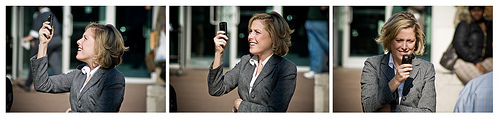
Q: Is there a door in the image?
A: Yes, there is a door.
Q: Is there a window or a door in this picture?
A: Yes, there is a door.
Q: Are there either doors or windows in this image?
A: Yes, there is a door.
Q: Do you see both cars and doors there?
A: No, there is a door but no cars.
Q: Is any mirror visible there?
A: No, there are no mirrors.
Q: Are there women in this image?
A: Yes, there is a woman.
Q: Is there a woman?
A: Yes, there is a woman.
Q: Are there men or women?
A: Yes, there is a woman.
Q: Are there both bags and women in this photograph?
A: Yes, there are both a woman and a bag.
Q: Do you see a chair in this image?
A: No, there are no chairs.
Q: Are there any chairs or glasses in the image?
A: No, there are no chairs or glasses.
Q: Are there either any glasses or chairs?
A: No, there are no chairs or glasses.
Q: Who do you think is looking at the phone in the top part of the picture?
A: The woman is looking at the telephone.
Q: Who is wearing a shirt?
A: The woman is wearing a shirt.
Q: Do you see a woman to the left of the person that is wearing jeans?
A: Yes, there is a woman to the left of the person.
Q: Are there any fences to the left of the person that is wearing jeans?
A: No, there is a woman to the left of the person.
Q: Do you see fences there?
A: No, there are no fences.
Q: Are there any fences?
A: No, there are no fences.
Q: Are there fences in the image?
A: No, there are no fences.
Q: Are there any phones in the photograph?
A: Yes, there is a phone.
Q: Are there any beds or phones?
A: Yes, there is a phone.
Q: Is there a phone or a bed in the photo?
A: Yes, there is a phone.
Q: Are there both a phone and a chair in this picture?
A: No, there is a phone but no chairs.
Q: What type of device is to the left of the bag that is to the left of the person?
A: The device is a phone.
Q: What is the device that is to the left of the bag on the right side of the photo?
A: The device is a phone.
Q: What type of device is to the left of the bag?
A: The device is a phone.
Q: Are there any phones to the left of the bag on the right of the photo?
A: Yes, there is a phone to the left of the bag.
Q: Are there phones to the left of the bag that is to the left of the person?
A: Yes, there is a phone to the left of the bag.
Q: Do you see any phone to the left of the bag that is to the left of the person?
A: Yes, there is a phone to the left of the bag.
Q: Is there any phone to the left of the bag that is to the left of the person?
A: Yes, there is a phone to the left of the bag.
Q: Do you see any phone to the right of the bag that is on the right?
A: No, the phone is to the left of the bag.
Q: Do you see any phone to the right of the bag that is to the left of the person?
A: No, the phone is to the left of the bag.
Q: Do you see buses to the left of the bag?
A: No, there is a phone to the left of the bag.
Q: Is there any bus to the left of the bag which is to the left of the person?
A: No, there is a phone to the left of the bag.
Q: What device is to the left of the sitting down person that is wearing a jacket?
A: The device is a phone.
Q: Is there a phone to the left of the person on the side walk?
A: Yes, there is a phone to the left of the person.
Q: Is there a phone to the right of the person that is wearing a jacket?
A: No, the phone is to the left of the person.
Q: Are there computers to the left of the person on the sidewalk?
A: No, there is a phone to the left of the person.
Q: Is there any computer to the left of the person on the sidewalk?
A: No, there is a phone to the left of the person.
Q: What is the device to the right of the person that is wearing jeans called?
A: The device is a phone.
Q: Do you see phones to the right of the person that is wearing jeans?
A: Yes, there is a phone to the right of the person.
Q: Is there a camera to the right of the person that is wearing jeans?
A: No, there is a phone to the right of the person.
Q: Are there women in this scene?
A: Yes, there is a woman.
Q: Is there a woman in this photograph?
A: Yes, there is a woman.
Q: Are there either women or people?
A: Yes, there is a woman.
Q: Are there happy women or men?
A: Yes, there is a happy woman.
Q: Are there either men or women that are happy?
A: Yes, the woman is happy.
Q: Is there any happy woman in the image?
A: Yes, there is a happy woman.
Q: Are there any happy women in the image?
A: Yes, there is a happy woman.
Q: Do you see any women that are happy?
A: Yes, there is a happy woman.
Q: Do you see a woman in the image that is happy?
A: Yes, there is a woman that is happy.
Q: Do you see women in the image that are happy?
A: Yes, there is a woman that is happy.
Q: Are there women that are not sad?
A: Yes, there is a happy woman.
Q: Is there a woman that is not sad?
A: Yes, there is a happy woman.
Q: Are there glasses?
A: No, there are no glasses.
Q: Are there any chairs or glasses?
A: No, there are no glasses or chairs.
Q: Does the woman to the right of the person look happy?
A: Yes, the woman is happy.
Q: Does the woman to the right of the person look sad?
A: No, the woman is happy.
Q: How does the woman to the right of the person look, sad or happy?
A: The woman is happy.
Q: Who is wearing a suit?
A: The woman is wearing a suit.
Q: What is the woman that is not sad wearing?
A: The woman is wearing a suit.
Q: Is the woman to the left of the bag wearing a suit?
A: Yes, the woman is wearing a suit.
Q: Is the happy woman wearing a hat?
A: No, the woman is wearing a suit.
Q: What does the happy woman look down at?
A: The woman looks down at the telephone.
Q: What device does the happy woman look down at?
A: The woman looks down at the phone.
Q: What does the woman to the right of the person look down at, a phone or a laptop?
A: The woman looks down at a phone.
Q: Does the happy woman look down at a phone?
A: Yes, the woman looks down at a phone.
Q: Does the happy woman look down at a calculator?
A: No, the woman looks down at a phone.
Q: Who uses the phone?
A: The woman uses the phone.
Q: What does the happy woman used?
A: The woman uses a phone.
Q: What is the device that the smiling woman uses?
A: The device is a phone.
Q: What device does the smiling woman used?
A: The woman uses a telephone.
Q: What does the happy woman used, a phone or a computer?
A: The woman uses a phone.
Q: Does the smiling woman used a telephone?
A: Yes, the woman uses a telephone.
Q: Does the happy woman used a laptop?
A: No, the woman uses a telephone.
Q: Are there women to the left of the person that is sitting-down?
A: Yes, there is a woman to the left of the person.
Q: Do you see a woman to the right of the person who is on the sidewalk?
A: No, the woman is to the left of the person.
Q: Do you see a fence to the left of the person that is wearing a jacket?
A: No, there is a woman to the left of the person.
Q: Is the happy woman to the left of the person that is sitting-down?
A: Yes, the woman is to the left of the person.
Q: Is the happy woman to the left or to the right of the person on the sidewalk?
A: The woman is to the left of the person.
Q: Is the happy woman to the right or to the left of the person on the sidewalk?
A: The woman is to the left of the person.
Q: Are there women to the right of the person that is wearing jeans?
A: Yes, there is a woman to the right of the person.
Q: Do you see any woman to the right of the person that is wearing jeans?
A: Yes, there is a woman to the right of the person.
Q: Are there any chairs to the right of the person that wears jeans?
A: No, there is a woman to the right of the person.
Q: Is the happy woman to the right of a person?
A: Yes, the woman is to the right of a person.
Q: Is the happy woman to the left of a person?
A: No, the woman is to the right of a person.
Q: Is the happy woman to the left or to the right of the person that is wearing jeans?
A: The woman is to the right of the person.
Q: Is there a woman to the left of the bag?
A: Yes, there is a woman to the left of the bag.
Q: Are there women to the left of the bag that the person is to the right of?
A: Yes, there is a woman to the left of the bag.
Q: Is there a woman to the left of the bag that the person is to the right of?
A: Yes, there is a woman to the left of the bag.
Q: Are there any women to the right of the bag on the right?
A: No, the woman is to the left of the bag.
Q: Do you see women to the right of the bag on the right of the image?
A: No, the woman is to the left of the bag.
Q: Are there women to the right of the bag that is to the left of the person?
A: No, the woman is to the left of the bag.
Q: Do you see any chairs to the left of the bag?
A: No, there is a woman to the left of the bag.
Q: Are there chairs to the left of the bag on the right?
A: No, there is a woman to the left of the bag.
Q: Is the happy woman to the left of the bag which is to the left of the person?
A: Yes, the woman is to the left of the bag.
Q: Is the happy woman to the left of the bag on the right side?
A: Yes, the woman is to the left of the bag.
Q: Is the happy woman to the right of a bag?
A: No, the woman is to the left of a bag.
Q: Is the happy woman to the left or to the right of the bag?
A: The woman is to the left of the bag.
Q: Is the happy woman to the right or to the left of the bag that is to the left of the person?
A: The woman is to the left of the bag.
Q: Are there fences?
A: No, there are no fences.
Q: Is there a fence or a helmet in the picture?
A: No, there are no fences or helmets.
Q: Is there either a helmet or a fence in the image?
A: No, there are no fences or helmets.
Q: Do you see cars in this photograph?
A: No, there are no cars.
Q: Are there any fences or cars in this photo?
A: No, there are no cars or fences.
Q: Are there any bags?
A: Yes, there is a bag.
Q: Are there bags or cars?
A: Yes, there is a bag.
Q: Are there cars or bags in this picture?
A: Yes, there is a bag.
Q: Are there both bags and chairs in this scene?
A: No, there is a bag but no chairs.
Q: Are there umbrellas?
A: No, there are no umbrellas.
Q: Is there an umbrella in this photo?
A: No, there are no umbrellas.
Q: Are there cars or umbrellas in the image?
A: No, there are no umbrellas or cars.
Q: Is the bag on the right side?
A: Yes, the bag is on the right of the image.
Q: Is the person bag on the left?
A: No, the bag is on the right of the image.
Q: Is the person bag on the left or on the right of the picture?
A: The bag is on the right of the image.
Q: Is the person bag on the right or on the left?
A: The bag is on the right of the image.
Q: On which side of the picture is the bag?
A: The bag is on the right of the image.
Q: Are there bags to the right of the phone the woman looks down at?
A: Yes, there is a bag to the right of the phone.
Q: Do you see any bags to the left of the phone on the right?
A: No, the bag is to the right of the phone.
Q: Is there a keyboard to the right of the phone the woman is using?
A: No, there is a bag to the right of the telephone.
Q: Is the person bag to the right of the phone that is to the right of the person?
A: Yes, the bag is to the right of the phone.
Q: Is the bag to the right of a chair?
A: No, the bag is to the right of the phone.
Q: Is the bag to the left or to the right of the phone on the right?
A: The bag is to the right of the telephone.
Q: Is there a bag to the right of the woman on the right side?
A: Yes, there is a bag to the right of the woman.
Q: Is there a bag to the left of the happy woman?
A: No, the bag is to the right of the woman.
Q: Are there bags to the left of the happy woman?
A: No, the bag is to the right of the woman.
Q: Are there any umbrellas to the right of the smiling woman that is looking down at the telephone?
A: No, there is a bag to the right of the woman.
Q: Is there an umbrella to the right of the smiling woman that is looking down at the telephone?
A: No, there is a bag to the right of the woman.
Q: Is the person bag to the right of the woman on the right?
A: Yes, the bag is to the right of the woman.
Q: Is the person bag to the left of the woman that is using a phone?
A: No, the bag is to the right of the woman.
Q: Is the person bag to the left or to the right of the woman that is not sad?
A: The bag is to the right of the woman.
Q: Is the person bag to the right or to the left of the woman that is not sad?
A: The bag is to the right of the woman.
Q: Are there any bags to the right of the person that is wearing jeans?
A: Yes, there is a bag to the right of the person.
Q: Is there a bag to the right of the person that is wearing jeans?
A: Yes, there is a bag to the right of the person.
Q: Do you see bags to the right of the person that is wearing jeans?
A: Yes, there is a bag to the right of the person.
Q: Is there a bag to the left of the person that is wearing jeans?
A: No, the bag is to the right of the person.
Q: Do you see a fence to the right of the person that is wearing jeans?
A: No, there is a bag to the right of the person.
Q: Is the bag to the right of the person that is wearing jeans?
A: Yes, the bag is to the right of the person.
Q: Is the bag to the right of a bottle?
A: No, the bag is to the right of the person.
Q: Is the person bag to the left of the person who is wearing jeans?
A: No, the bag is to the right of the person.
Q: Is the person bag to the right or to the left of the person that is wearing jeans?
A: The bag is to the right of the person.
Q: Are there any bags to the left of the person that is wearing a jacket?
A: Yes, there is a bag to the left of the person.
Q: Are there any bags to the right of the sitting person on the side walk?
A: No, the bag is to the left of the person.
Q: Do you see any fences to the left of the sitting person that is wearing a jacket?
A: No, there is a bag to the left of the person.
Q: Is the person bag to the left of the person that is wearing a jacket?
A: Yes, the bag is to the left of the person.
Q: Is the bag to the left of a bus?
A: No, the bag is to the left of the person.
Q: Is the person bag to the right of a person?
A: No, the bag is to the left of a person.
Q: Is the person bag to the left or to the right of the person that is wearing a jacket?
A: The bag is to the left of the person.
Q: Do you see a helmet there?
A: No, there are no helmets.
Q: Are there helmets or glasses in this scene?
A: No, there are no helmets or glasses.